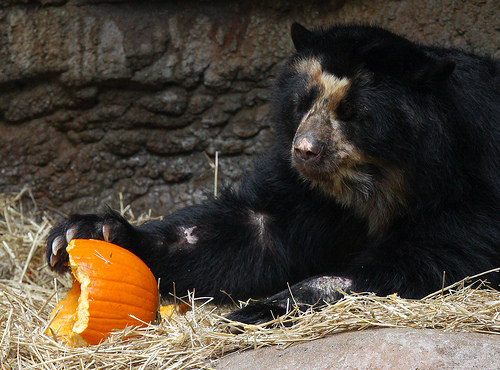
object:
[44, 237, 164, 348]
fruit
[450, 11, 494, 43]
wall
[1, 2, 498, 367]
day time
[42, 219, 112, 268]
claws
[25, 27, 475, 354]
scene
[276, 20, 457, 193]
head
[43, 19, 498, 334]
animal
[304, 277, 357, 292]
spot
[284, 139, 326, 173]
nose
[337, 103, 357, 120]
eye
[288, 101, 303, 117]
eye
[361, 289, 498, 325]
hay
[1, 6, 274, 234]
wall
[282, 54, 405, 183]
face